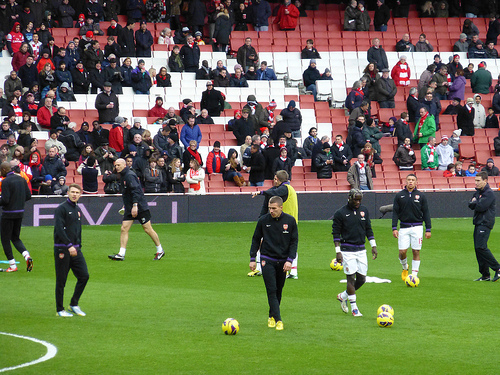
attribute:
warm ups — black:
[247, 214, 300, 321]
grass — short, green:
[30, 220, 481, 351]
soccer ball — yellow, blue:
[358, 303, 405, 338]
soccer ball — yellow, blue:
[396, 265, 428, 295]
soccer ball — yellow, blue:
[314, 242, 354, 286]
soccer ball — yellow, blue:
[371, 293, 408, 315]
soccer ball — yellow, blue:
[186, 300, 268, 365]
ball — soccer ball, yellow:
[376, 302, 395, 320]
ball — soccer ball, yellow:
[374, 312, 394, 327]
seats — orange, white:
[0, 0, 499, 191]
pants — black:
[262, 257, 290, 322]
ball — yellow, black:
[221, 317, 239, 337]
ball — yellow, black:
[376, 310, 394, 327]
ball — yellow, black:
[377, 302, 395, 317]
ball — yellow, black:
[402, 272, 420, 289]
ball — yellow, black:
[330, 255, 344, 273]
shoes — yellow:
[262, 315, 297, 333]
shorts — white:
[373, 227, 433, 262]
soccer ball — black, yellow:
[221, 316, 238, 335]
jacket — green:
[412, 113, 436, 144]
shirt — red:
[416, 111, 428, 131]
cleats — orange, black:
[17, 254, 49, 277]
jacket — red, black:
[205, 149, 224, 172]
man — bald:
[107, 158, 166, 260]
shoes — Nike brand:
[108, 248, 165, 260]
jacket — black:
[389, 191, 431, 226]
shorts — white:
[397, 226, 424, 254]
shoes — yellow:
[399, 271, 412, 281]